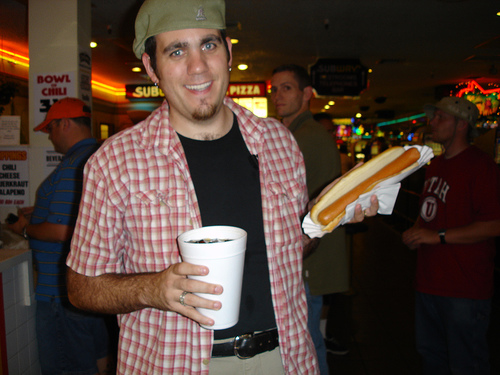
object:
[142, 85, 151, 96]
u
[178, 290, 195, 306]
band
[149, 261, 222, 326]
hand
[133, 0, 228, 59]
hat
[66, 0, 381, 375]
man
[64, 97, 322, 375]
shirt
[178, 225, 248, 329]
cup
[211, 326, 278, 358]
belt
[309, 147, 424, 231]
hotdog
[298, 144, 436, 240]
towel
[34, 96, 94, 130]
hat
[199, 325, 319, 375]
pants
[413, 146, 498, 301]
shirt